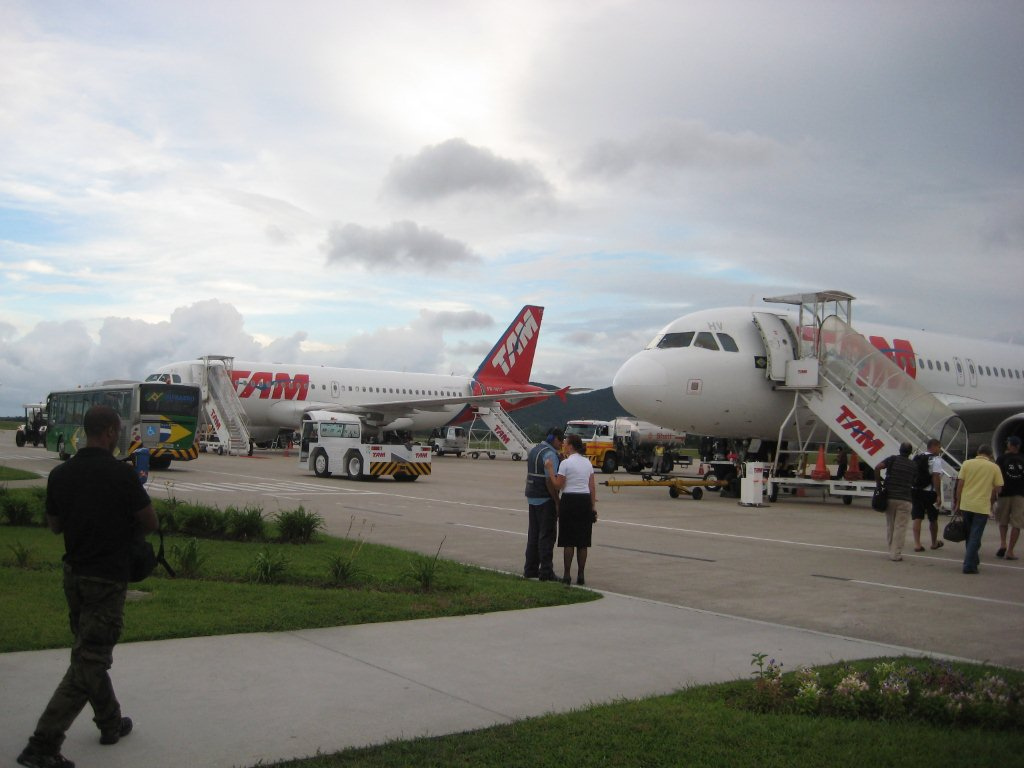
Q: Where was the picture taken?
A: At an airport.